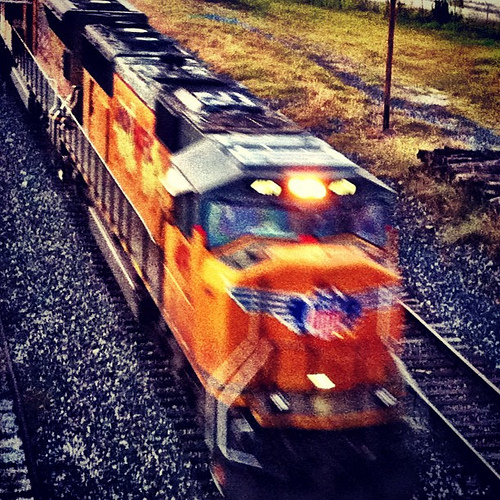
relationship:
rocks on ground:
[0, 78, 222, 500] [427, 203, 474, 242]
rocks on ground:
[391, 194, 498, 431] [4, 2, 494, 498]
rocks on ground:
[0, 78, 222, 500] [206, 32, 493, 175]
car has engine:
[0, 0, 410, 499] [255, 245, 382, 301]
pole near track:
[382, 0, 396, 129] [390, 295, 499, 484]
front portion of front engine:
[232, 260, 412, 398] [199, 252, 411, 468]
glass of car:
[205, 196, 387, 250] [0, 0, 410, 499]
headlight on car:
[250, 174, 357, 201] [0, 0, 410, 499]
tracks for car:
[81, 1, 498, 476] [0, 0, 410, 499]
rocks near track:
[23, 287, 121, 445] [35, 67, 484, 461]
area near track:
[139, 4, 480, 205] [48, 83, 497, 484]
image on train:
[223, 273, 408, 349] [20, 14, 418, 465]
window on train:
[205, 197, 391, 260] [1, 2, 410, 498]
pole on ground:
[370, 1, 400, 139] [134, 2, 484, 235]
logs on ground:
[417, 136, 499, 166] [156, 8, 484, 261]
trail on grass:
[218, 11, 468, 145] [130, 2, 498, 246]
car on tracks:
[0, 0, 410, 499] [99, 63, 482, 483]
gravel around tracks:
[25, 271, 130, 454] [98, 85, 476, 457]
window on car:
[205, 193, 391, 250] [6, 4, 426, 449]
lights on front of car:
[207, 374, 322, 436] [0, 0, 410, 499]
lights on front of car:
[300, 354, 447, 457] [0, 0, 410, 499]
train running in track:
[20, 14, 418, 465] [363, 302, 483, 482]